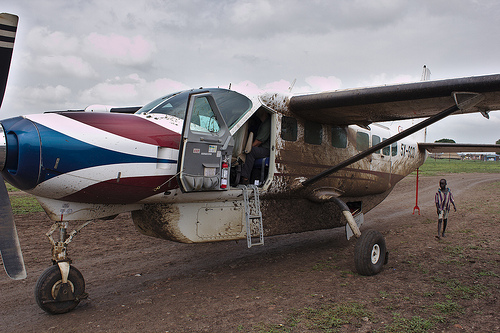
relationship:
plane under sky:
[4, 71, 500, 311] [1, 4, 499, 135]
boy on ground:
[427, 172, 465, 244] [0, 178, 497, 330]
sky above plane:
[1, 4, 499, 135] [4, 71, 500, 311]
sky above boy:
[1, 4, 499, 135] [427, 172, 465, 244]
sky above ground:
[1, 4, 499, 135] [0, 178, 497, 330]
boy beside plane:
[427, 172, 465, 244] [4, 71, 500, 311]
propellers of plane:
[4, 167, 37, 294] [0, 12, 500, 316]